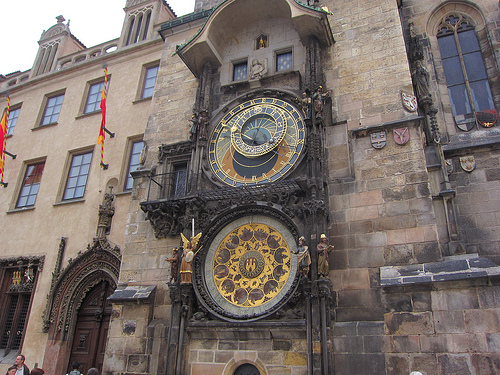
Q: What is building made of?
A: Sandstone.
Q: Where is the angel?
A: Bottom circle, left side.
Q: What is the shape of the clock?
A: Round.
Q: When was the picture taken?
A: Daytime.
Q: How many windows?
A: 11.